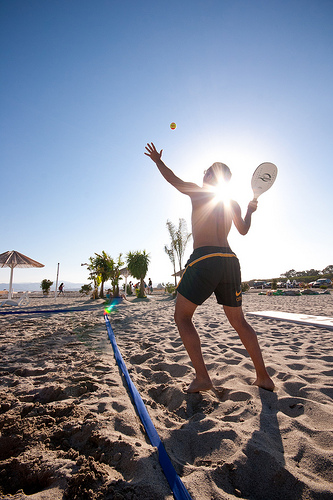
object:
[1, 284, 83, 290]
water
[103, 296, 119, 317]
prism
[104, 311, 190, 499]
blue line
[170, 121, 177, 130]
ball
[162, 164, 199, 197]
arm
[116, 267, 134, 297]
umbrella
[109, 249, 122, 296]
tree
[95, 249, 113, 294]
tree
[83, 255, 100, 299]
tree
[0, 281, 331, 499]
beach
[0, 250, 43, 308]
umbrella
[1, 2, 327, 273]
air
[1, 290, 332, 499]
sand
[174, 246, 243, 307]
shorts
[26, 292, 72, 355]
beach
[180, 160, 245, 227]
sun rays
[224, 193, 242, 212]
shoulder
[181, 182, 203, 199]
shoulder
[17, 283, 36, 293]
mountain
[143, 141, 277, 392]
guy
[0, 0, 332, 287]
sky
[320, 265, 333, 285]
trees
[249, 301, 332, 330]
board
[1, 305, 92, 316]
rope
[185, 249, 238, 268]
stripes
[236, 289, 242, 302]
nike logo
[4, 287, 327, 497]
ground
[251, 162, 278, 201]
paddle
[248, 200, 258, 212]
hand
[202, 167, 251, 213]
sun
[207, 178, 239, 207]
glare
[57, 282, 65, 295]
people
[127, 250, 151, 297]
palms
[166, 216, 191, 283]
palms